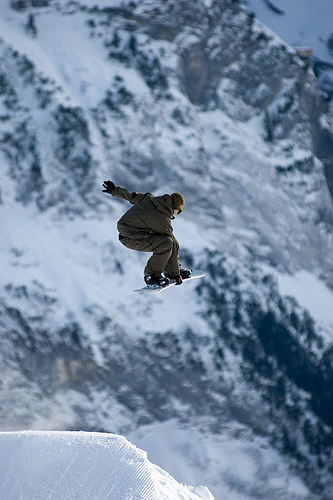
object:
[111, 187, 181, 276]
sweater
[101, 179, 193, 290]
skier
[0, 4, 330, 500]
snow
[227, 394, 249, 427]
building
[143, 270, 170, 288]
shoe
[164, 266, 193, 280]
shoe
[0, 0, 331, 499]
mountain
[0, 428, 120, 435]
snow wedge